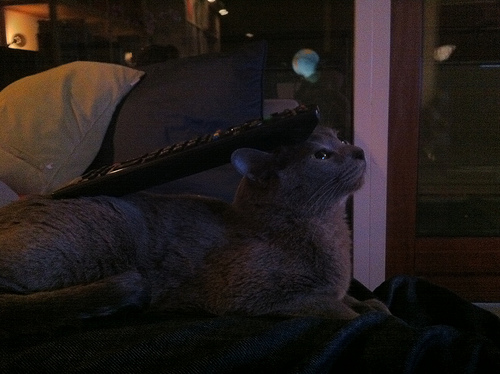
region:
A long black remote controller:
[30, 106, 351, 203]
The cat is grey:
[8, 110, 406, 329]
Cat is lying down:
[20, 123, 390, 314]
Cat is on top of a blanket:
[11, 110, 402, 313]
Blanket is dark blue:
[27, 201, 449, 367]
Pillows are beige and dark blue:
[20, 36, 277, 183]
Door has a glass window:
[374, 8, 478, 288]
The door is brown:
[383, 11, 475, 295]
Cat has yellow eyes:
[292, 119, 374, 168]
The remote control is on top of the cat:
[29, 108, 409, 324]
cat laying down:
[2, 125, 393, 341]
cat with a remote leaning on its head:
[3, 101, 391, 326]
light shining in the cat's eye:
[322, 151, 327, 157]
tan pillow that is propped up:
[2, 47, 139, 205]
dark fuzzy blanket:
[1, 272, 487, 367]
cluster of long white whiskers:
[303, 171, 346, 242]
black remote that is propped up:
[40, 98, 337, 230]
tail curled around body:
[0, 259, 157, 324]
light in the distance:
[6, 8, 54, 45]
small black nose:
[351, 146, 366, 163]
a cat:
[200, 137, 307, 258]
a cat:
[239, 217, 285, 277]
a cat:
[272, 202, 296, 244]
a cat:
[281, 261, 308, 318]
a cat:
[239, 190, 300, 316]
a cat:
[243, 222, 312, 372]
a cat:
[216, 212, 289, 339]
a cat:
[233, 247, 279, 358]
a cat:
[162, 133, 276, 329]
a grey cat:
[8, 117, 376, 335]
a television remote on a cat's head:
[52, 96, 322, 209]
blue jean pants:
[12, 275, 493, 368]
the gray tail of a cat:
[6, 264, 159, 336]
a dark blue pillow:
[106, 31, 280, 162]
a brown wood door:
[383, 3, 498, 303]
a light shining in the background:
[0, 29, 24, 55]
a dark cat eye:
[314, 150, 329, 159]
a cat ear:
[230, 140, 282, 176]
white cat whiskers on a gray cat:
[298, 172, 344, 227]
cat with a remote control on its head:
[5, 102, 408, 331]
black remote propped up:
[56, 91, 331, 208]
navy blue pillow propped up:
[93, 58, 292, 205]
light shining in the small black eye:
[320, 150, 327, 161]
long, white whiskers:
[304, 172, 354, 251]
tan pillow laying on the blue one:
[3, 56, 159, 198]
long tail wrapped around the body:
[3, 265, 160, 317]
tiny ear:
[228, 144, 288, 187]